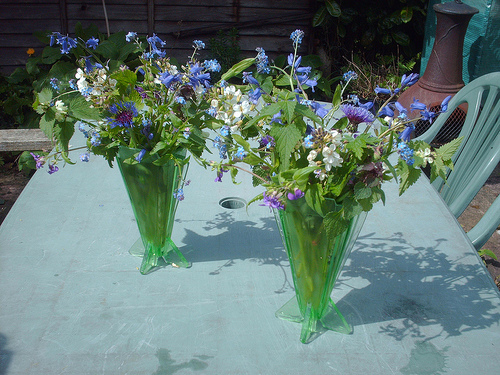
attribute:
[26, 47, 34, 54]
flower — orange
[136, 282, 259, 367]
table — white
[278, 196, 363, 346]
vase — green, glass, clear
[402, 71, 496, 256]
chair — plastic, white, green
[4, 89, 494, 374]
plastic tabletop — green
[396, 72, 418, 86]
flower — blue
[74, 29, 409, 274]
flowers — blue, white, green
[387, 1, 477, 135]
heater — patio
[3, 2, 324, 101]
fence — wooden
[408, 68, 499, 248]
chair — green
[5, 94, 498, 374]
table — blue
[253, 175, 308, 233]
flower — bright, purple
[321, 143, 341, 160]
flowers — purple, white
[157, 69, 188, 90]
flowers — white, purple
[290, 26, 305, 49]
flowers — purple, white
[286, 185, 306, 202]
flowers — white, purple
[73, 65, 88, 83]
flowers — purple, white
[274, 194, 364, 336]
vase — green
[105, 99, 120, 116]
flower — blue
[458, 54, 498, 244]
chair — blue 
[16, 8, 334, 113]
fence — wood, brown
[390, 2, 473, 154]
fireplace — small, brown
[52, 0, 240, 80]
fence — wooden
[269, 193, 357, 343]
vase — clear, green, glass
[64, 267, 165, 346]
table — blue